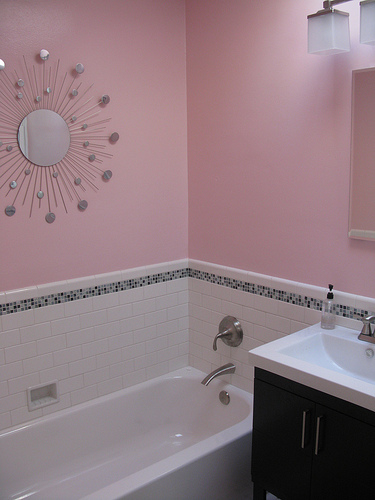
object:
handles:
[299, 400, 322, 458]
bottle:
[317, 276, 339, 332]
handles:
[296, 407, 325, 457]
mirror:
[343, 64, 375, 241]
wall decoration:
[0, 33, 121, 233]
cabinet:
[251, 362, 374, 499]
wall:
[2, 0, 186, 361]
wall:
[188, 2, 374, 284]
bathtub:
[0, 361, 261, 499]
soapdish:
[23, 376, 61, 412]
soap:
[319, 280, 340, 331]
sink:
[245, 313, 374, 415]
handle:
[207, 312, 245, 357]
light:
[310, 7, 350, 60]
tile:
[154, 293, 178, 310]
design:
[0, 43, 122, 227]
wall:
[0, 2, 375, 301]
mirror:
[14, 99, 76, 172]